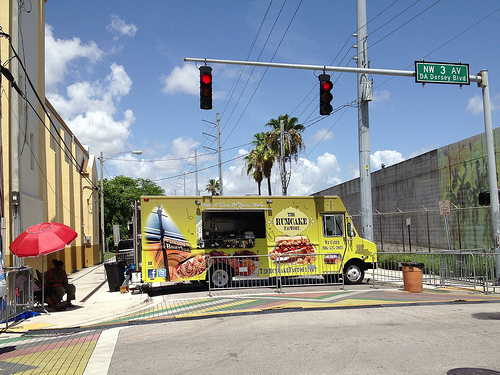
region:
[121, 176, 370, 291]
YELLOW TRUCK NEAR SIGNALS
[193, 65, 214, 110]
TRAFFIC SIGNAL OVER ROAD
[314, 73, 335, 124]
TRAFFIC SIGNAL OVER ROAD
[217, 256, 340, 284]
METAL GATE BY TRUCK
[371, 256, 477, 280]
METAL GATE BY TRUCK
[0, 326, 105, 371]
YELLOW CROSSWALK OF ROAD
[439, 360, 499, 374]
ROUND MANHOLE COVER ON ROAD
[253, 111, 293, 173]
PALM TREES BEHIND TRUCK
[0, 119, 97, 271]
TALL BUILDING ON LEFT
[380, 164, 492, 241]
LARGE BUILDING ON RIGHT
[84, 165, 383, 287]
food truck on the street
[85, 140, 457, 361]
a truck on the road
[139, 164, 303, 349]
a truck on the street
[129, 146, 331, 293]
a large truck on the road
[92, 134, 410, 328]
a large truck on the street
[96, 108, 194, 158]
a sky that is blue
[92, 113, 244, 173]
a sky with clouds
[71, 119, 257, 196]
a sky with white clouds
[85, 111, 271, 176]
a blue sky with clouds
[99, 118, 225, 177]
a blue sky with white clouds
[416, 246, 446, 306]
a garbage can outside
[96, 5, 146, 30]
this is the sky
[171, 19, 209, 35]
the sky is blue in color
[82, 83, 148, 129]
the sky has clouds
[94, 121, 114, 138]
the clouds are white in color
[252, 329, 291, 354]
this is the road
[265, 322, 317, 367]
the road is grey in color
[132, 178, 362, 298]
this is a van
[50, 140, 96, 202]
this is a building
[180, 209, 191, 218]
the van is yellow in color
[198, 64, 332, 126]
these are traffic lights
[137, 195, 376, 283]
yellow decorated food truck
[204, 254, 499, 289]
grey metal barrier fence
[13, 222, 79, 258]
red fabric patio umbrella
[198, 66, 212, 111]
black stop light on pole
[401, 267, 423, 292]
terra cotta flower pot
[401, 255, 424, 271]
green plant in flower pot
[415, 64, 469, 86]
green and white street sign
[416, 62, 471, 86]
street sign on pole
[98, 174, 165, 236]
tree with green leaves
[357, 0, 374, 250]
grey metal electrical pole